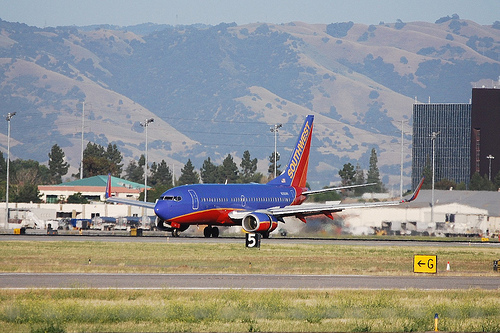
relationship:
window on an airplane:
[156, 190, 182, 206] [81, 106, 436, 250]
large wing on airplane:
[265, 177, 427, 217] [109, 112, 423, 237]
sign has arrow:
[413, 254, 436, 274] [415, 260, 427, 267]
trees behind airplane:
[10, 143, 268, 179] [130, 110, 428, 225]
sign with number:
[244, 233, 261, 248] [246, 231, 256, 246]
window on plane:
[199, 197, 211, 205] [104, 113, 428, 234]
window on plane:
[250, 192, 265, 202] [104, 113, 428, 234]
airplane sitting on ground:
[109, 112, 423, 237] [34, 235, 487, 325]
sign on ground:
[236, 226, 266, 252] [0, 244, 397, 270]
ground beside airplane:
[0, 244, 397, 270] [133, 139, 395, 274]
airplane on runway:
[109, 112, 423, 237] [0, 233, 498, 247]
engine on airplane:
[239, 209, 278, 231] [109, 112, 423, 237]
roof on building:
[58, 174, 150, 188] [33, 172, 153, 199]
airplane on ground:
[109, 112, 423, 237] [24, 243, 465, 269]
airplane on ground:
[109, 112, 423, 237] [0, 237, 499, 247]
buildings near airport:
[406, 75, 496, 202] [10, 203, 495, 326]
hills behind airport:
[1, 3, 499, 178] [6, 173, 496, 330]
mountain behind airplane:
[13, 18, 493, 189] [109, 112, 423, 237]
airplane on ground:
[109, 112, 423, 237] [0, 244, 499, 305]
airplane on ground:
[109, 112, 423, 237] [167, 230, 412, 295]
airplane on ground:
[109, 112, 423, 237] [6, 155, 476, 325]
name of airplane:
[285, 120, 311, 177] [145, 115, 440, 237]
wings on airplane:
[263, 196, 440, 223] [119, 110, 347, 240]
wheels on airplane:
[206, 216, 305, 277] [85, 114, 381, 282]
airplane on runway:
[109, 112, 423, 237] [0, 235, 499, 242]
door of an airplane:
[186, 189, 201, 209] [104, 115, 378, 239]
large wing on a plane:
[100, 178, 155, 212] [104, 113, 428, 234]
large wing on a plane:
[265, 177, 427, 217] [104, 113, 428, 234]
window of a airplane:
[201, 198, 203, 201] [109, 112, 423, 237]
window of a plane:
[201, 198, 203, 201] [104, 113, 428, 234]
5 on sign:
[243, 232, 259, 246] [241, 231, 263, 248]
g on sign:
[422, 255, 436, 271] [410, 251, 440, 275]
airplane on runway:
[109, 112, 423, 237] [3, 271, 493, 286]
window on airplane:
[178, 196, 181, 201] [145, 115, 440, 237]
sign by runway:
[413, 254, 436, 274] [3, 280, 483, 290]